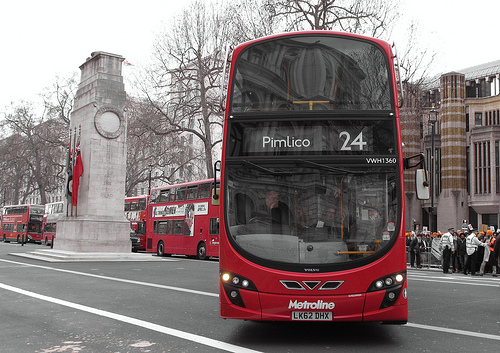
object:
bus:
[146, 178, 221, 265]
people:
[408, 226, 424, 269]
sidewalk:
[414, 256, 492, 278]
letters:
[253, 131, 315, 154]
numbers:
[338, 131, 352, 152]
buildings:
[51, 49, 129, 253]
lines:
[0, 283, 260, 352]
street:
[3, 239, 499, 353]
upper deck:
[151, 183, 220, 205]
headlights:
[220, 271, 232, 282]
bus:
[220, 35, 414, 321]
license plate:
[290, 309, 334, 323]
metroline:
[287, 298, 337, 312]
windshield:
[224, 36, 399, 266]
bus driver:
[255, 188, 292, 223]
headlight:
[370, 275, 408, 287]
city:
[1, 2, 496, 351]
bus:
[0, 202, 42, 244]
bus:
[126, 194, 149, 247]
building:
[405, 65, 500, 259]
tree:
[149, 3, 229, 184]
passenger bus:
[41, 201, 66, 247]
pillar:
[437, 71, 469, 245]